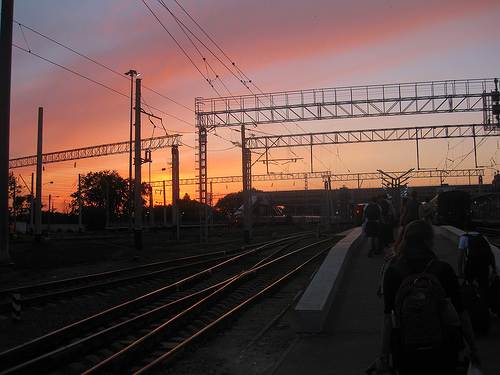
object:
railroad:
[1, 241, 267, 305]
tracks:
[1, 231, 318, 356]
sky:
[0, 0, 499, 213]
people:
[380, 218, 470, 372]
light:
[133, 67, 145, 81]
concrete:
[175, 226, 387, 374]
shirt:
[457, 231, 495, 260]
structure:
[197, 77, 499, 132]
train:
[228, 195, 369, 223]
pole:
[35, 102, 48, 214]